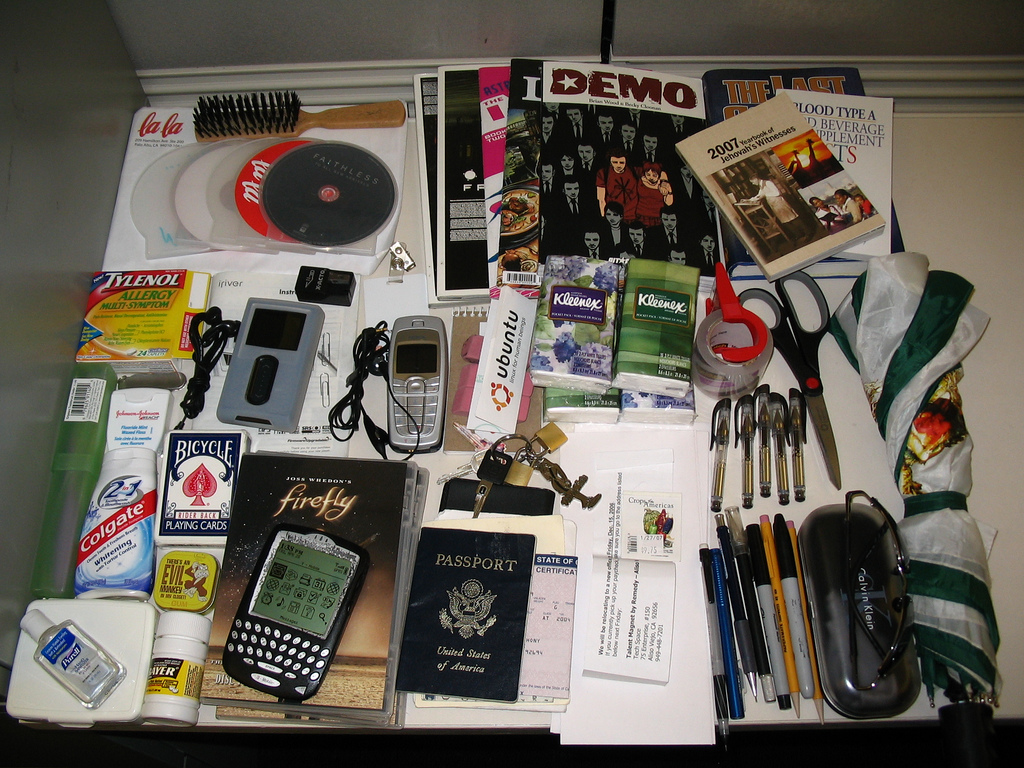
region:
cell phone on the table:
[378, 316, 451, 447]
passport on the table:
[389, 509, 532, 709]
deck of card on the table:
[147, 417, 246, 536]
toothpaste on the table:
[49, 423, 155, 591]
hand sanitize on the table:
[18, 610, 121, 713]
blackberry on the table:
[224, 512, 364, 696]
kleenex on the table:
[618, 255, 701, 455]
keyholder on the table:
[452, 418, 614, 533]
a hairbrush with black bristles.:
[189, 86, 408, 145]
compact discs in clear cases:
[126, 138, 401, 263]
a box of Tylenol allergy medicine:
[70, 262, 216, 367]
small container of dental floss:
[101, 380, 175, 457]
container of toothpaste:
[70, 440, 162, 596]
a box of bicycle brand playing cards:
[151, 427, 251, 546]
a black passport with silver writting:
[394, 524, 546, 708]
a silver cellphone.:
[381, 310, 452, 453]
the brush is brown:
[188, 92, 407, 140]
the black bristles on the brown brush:
[190, 91, 406, 140]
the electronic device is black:
[222, 525, 369, 696]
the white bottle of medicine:
[138, 607, 209, 728]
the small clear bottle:
[17, 607, 123, 709]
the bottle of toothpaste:
[74, 445, 163, 598]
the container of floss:
[105, 386, 176, 451]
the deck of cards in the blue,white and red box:
[156, 430, 246, 548]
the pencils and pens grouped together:
[700, 503, 825, 742]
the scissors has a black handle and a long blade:
[738, 266, 844, 491]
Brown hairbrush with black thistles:
[187, 83, 410, 147]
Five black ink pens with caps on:
[700, 377, 830, 518]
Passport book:
[383, 518, 546, 703]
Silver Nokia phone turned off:
[371, 306, 457, 455]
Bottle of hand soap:
[19, 601, 122, 713]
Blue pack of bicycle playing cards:
[152, 420, 247, 566]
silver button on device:
[319, 641, 329, 661]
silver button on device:
[304, 641, 325, 655]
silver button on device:
[300, 636, 310, 653]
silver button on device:
[286, 630, 302, 649]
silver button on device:
[304, 666, 320, 690]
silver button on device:
[297, 657, 313, 677]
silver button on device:
[253, 650, 288, 674]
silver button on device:
[244, 638, 258, 654]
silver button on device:
[241, 612, 252, 633]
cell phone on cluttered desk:
[385, 315, 449, 452]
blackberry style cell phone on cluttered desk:
[224, 523, 370, 711]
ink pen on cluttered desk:
[706, 398, 736, 515]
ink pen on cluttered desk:
[728, 390, 763, 514]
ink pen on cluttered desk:
[753, 379, 777, 501]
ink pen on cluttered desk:
[787, 387, 810, 505]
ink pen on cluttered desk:
[772, 393, 789, 510]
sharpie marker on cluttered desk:
[743, 518, 795, 722]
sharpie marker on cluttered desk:
[778, 534, 817, 706]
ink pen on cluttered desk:
[696, 539, 735, 751]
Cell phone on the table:
[209, 515, 381, 715]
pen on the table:
[733, 391, 754, 512]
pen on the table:
[710, 390, 731, 509]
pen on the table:
[770, 494, 809, 700]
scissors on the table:
[744, 264, 840, 503]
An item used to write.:
[707, 389, 718, 510]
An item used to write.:
[733, 392, 760, 525]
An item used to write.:
[768, 392, 803, 506]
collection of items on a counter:
[11, 60, 1020, 744]